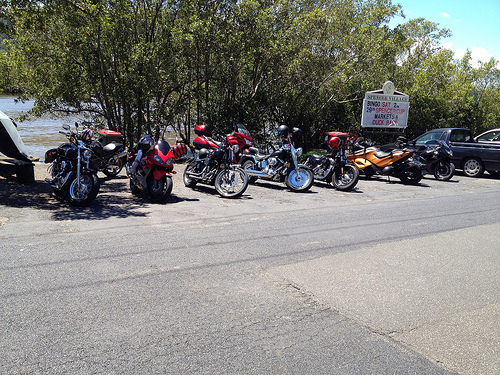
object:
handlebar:
[334, 133, 346, 140]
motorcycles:
[44, 124, 121, 210]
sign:
[360, 90, 411, 130]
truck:
[380, 128, 500, 176]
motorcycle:
[183, 135, 250, 198]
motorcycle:
[345, 135, 425, 186]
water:
[0, 97, 104, 161]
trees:
[0, 1, 499, 167]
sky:
[366, 0, 500, 69]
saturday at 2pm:
[364, 100, 406, 115]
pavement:
[0, 162, 500, 375]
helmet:
[325, 136, 341, 148]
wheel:
[287, 165, 311, 192]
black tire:
[212, 167, 250, 196]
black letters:
[365, 100, 373, 106]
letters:
[373, 105, 379, 111]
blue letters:
[374, 112, 381, 120]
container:
[15, 159, 36, 183]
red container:
[195, 121, 213, 136]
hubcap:
[73, 180, 90, 201]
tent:
[0, 113, 36, 188]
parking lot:
[0, 131, 499, 240]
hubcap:
[289, 168, 309, 190]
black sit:
[373, 146, 401, 158]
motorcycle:
[236, 123, 314, 193]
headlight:
[295, 147, 305, 155]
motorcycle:
[120, 135, 177, 200]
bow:
[46, 107, 106, 118]